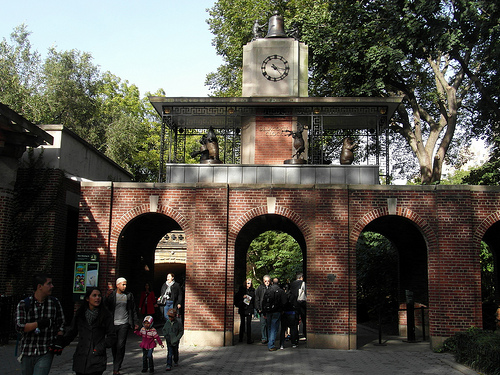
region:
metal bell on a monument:
[263, 8, 287, 39]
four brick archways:
[72, 179, 498, 349]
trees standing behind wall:
[0, 0, 496, 187]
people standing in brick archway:
[232, 269, 305, 351]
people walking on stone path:
[6, 272, 182, 373]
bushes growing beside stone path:
[449, 326, 499, 374]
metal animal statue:
[336, 133, 356, 166]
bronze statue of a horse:
[281, 119, 307, 163]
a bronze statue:
[186, 124, 223, 166]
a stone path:
[0, 339, 466, 372]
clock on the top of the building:
[255, 46, 297, 89]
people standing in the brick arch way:
[239, 256, 319, 353]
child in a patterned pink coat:
[130, 308, 174, 368]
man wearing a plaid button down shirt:
[10, 268, 83, 373]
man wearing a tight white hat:
[104, 270, 141, 365]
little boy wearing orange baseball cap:
[157, 301, 198, 374]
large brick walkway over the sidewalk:
[337, 197, 442, 374]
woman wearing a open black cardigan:
[152, 261, 185, 317]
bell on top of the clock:
[234, 6, 312, 52]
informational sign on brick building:
[67, 243, 112, 310]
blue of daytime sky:
[0, 0, 230, 107]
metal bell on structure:
[242, 9, 308, 94]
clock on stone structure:
[242, 37, 307, 92]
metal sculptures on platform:
[193, 119, 362, 184]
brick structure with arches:
[75, 182, 494, 350]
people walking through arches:
[231, 212, 310, 347]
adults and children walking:
[19, 271, 183, 373]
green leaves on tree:
[206, 33, 496, 185]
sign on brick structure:
[73, 250, 100, 292]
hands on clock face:
[271, 62, 286, 75]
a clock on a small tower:
[235, 33, 303, 95]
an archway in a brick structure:
[212, 199, 318, 356]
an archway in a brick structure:
[345, 195, 437, 356]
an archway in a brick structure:
[104, 201, 194, 346]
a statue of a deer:
[280, 110, 314, 172]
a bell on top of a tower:
[257, 8, 298, 41]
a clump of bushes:
[443, 338, 490, 368]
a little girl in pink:
[131, 303, 171, 374]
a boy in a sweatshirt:
[157, 310, 187, 362]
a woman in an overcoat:
[50, 300, 128, 369]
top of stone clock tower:
[240, 10, 315, 103]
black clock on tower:
[257, 52, 292, 87]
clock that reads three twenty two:
[257, 51, 291, 87]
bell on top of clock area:
[261, 6, 289, 41]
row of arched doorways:
[100, 203, 443, 360]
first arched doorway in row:
[109, 202, 192, 357]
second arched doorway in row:
[216, 198, 320, 351]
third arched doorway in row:
[347, 205, 440, 352]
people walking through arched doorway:
[232, 267, 314, 352]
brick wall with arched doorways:
[68, 172, 492, 364]